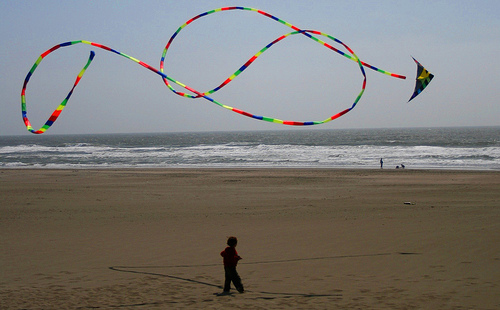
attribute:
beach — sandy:
[0, 166, 484, 308]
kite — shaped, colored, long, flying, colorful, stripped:
[17, 5, 433, 134]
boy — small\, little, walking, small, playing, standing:
[212, 231, 252, 302]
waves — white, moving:
[0, 140, 500, 171]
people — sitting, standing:
[376, 157, 408, 173]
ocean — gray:
[0, 123, 499, 170]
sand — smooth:
[320, 200, 401, 244]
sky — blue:
[1, 2, 499, 134]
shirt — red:
[221, 247, 243, 269]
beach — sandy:
[5, 166, 457, 230]